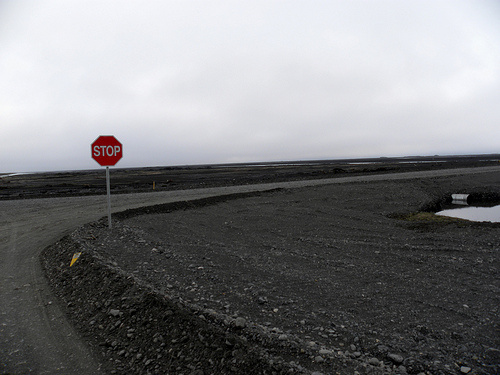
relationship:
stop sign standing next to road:
[90, 133, 124, 230] [1, 164, 484, 371]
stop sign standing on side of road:
[90, 133, 126, 231] [1, 164, 484, 371]